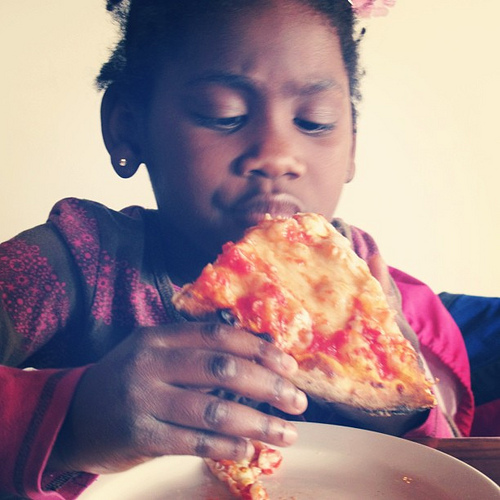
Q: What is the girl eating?
A: Pizza.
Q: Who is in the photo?
A: A girl.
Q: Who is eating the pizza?
A: The girl.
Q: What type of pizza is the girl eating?
A: Cheese.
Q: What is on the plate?
A: Chunk of pizza.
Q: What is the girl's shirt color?
A: Pink.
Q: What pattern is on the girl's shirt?
A: Stars and dots.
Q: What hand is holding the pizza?
A: Right hand.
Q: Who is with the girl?
A: Nobody.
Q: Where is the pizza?
A: In the child's hand.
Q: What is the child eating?
A: Pizza.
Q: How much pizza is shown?
A: One slice.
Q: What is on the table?
A: A plate.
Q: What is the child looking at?
A: A slice of pizza.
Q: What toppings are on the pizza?
A: Cheese and sauce.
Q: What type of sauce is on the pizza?
A: Tomato sauce.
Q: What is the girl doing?
A: Eating pizza.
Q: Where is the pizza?
A: In girl's hand.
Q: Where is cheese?
A: On the pizza.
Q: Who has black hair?
A: The girl.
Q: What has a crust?
A: The pizza.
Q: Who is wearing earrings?
A: Little girl.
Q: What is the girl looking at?
A: Pizza slice.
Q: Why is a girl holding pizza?
A: To eat it.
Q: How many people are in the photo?
A: One.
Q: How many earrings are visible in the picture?
A: One.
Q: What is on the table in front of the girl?
A: Plate.